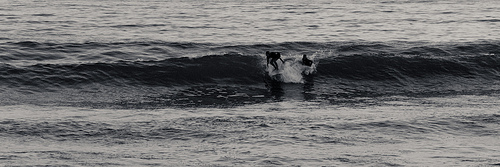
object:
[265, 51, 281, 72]
surfers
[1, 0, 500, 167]
water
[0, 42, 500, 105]
wave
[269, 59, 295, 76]
surfboards